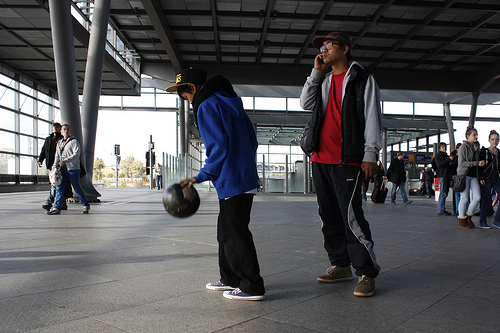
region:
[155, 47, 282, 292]
boy bouncing a ball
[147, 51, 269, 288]
boy wearing a blue jacket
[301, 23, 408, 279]
man holding a cell phone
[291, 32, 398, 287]
man wearing a red t-shirt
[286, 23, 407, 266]
man wearing a black and grey jacket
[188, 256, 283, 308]
grey and white tennis shoes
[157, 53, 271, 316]
boy wearing a black baseball hat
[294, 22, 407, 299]
man wearing a baseball hat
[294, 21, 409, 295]
man wearing glasses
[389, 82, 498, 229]
people standing in the background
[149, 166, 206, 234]
the ball is blackish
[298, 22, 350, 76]
older boy wearing glasses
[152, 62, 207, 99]
boy wearing a baseball hat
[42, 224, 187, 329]
the floor is grey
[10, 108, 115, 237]
2 men are walking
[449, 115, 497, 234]
2 girls standing around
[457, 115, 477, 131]
girl wearing a bun on her head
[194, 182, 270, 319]
boy wearing black pants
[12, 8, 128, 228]
2 huge grey pillars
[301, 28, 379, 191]
Male in red shirt using cell phone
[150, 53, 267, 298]
Male in blue jacket bouncing ball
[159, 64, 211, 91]
Black hat with yellow underside bill and writing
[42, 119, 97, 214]
Two people walking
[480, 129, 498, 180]
Girl facing the camera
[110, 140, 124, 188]
Sign on a post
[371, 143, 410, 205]
Person walking while pulling luggage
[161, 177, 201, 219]
Brown bouncing ball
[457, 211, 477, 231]
Brown boots with beige fleece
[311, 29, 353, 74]
Male with hat and glasses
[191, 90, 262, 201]
the boy is wearing a blue jacket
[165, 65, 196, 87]
the boy is wearing a hat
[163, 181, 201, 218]
the boy is holding a ball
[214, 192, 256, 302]
the boy is wearing black pants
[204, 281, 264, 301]
the boy is wearing sneakers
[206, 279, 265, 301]
the sneakers are black and white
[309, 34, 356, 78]
the boy is using a cell phone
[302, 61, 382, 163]
the boy is wearing a sweatshirt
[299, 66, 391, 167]
the sweatshirt is grey in color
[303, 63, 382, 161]
the boy is wearing a vest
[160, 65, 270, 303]
a young boy bouncing a ball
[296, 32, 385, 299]
a young man on cell phone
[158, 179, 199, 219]
a black basketball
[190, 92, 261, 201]
a dark blue jacket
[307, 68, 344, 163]
a red t-shirt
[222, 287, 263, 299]
a grey and white athletic shoe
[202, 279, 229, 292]
a grey and white athletic shoe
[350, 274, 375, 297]
a brown and white athletic shoe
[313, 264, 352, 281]
a brown and white athletic shoe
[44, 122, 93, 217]
a man walking